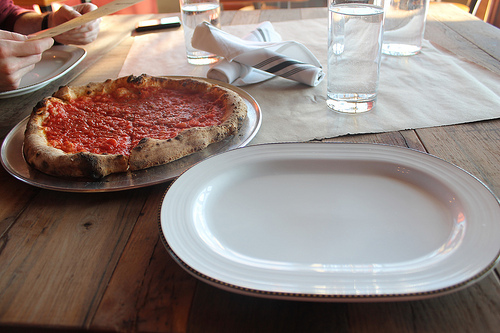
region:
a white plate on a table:
[154, 133, 499, 295]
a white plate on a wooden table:
[155, 138, 498, 302]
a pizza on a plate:
[3, 63, 262, 197]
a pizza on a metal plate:
[2, 74, 270, 199]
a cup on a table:
[325, 3, 382, 116]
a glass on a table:
[178, 0, 220, 65]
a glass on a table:
[358, 0, 433, 58]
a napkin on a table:
[181, 22, 324, 90]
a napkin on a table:
[203, 20, 283, 83]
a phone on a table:
[128, 15, 186, 32]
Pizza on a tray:
[20, 70, 248, 181]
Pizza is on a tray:
[20, 67, 252, 186]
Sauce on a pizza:
[42, 70, 227, 160]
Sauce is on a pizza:
[42, 76, 227, 165]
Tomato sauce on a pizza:
[43, 78, 228, 160]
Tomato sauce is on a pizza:
[45, 81, 228, 158]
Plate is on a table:
[148, 135, 497, 307]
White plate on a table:
[153, 134, 498, 307]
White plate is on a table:
[154, 137, 498, 309]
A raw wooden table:
[22, 263, 154, 332]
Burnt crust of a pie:
[78, 154, 106, 176]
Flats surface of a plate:
[262, 174, 402, 257]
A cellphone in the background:
[130, 12, 181, 36]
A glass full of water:
[324, 0, 391, 27]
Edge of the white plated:
[198, 265, 249, 301]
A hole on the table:
[77, 216, 100, 232]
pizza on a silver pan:
[0, 70, 262, 190]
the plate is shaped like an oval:
[155, 139, 499, 300]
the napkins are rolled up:
[186, 20, 326, 94]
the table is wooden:
[2, 2, 496, 332]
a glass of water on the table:
[323, 0, 385, 114]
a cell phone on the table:
[131, 12, 182, 36]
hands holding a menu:
[1, 0, 158, 91]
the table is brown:
[9, 0, 499, 327]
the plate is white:
[160, 144, 497, 303]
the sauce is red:
[46, 84, 223, 154]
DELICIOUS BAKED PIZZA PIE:
[13, 70, 253, 177]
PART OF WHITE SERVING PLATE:
[268, 185, 328, 225]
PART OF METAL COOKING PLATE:
[70, 183, 121, 190]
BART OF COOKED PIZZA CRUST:
[31, 144, 81, 175]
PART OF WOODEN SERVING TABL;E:
[26, 243, 111, 323]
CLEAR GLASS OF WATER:
[312, 0, 390, 116]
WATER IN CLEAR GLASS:
[377, 0, 430, 57]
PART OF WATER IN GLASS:
[178, 3, 219, 20]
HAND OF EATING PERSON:
[1, 27, 53, 97]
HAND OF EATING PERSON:
[47, 0, 102, 48]